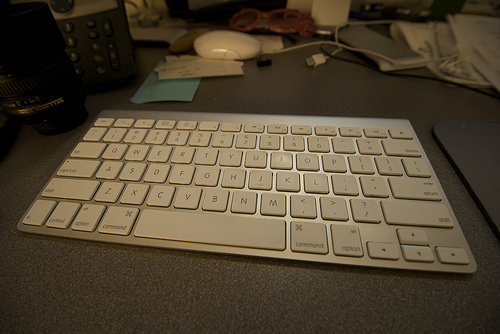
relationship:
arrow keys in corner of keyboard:
[365, 240, 400, 261] [118, 91, 479, 274]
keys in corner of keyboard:
[399, 227, 427, 244] [118, 91, 479, 274]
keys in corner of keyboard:
[436, 245, 467, 264] [118, 91, 479, 274]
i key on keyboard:
[272, 150, 292, 170] [18, 100, 475, 279]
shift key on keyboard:
[379, 199, 454, 225] [18, 100, 475, 279]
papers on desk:
[397, 22, 497, 82] [226, 274, 389, 328]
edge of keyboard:
[18, 221, 478, 271] [12, 108, 478, 276]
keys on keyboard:
[93, 134, 248, 166] [18, 100, 475, 279]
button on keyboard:
[329, 222, 363, 258] [18, 100, 475, 279]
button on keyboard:
[329, 222, 363, 258] [25, 87, 472, 309]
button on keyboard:
[289, 219, 329, 255] [18, 100, 475, 279]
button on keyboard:
[117, 160, 148, 182] [18, 100, 475, 279]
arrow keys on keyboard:
[365, 225, 470, 270] [74, 103, 472, 278]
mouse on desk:
[192, 29, 265, 60] [399, 52, 499, 129]